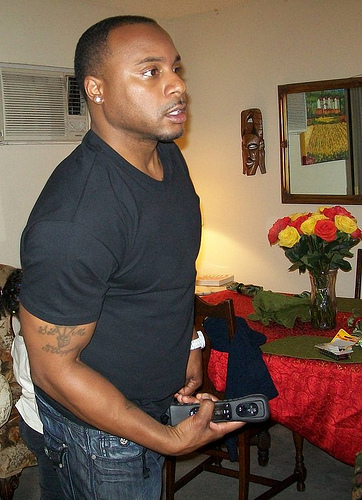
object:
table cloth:
[203, 285, 332, 429]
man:
[12, 8, 243, 497]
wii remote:
[162, 382, 276, 437]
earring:
[81, 68, 107, 109]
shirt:
[13, 127, 215, 430]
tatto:
[31, 319, 90, 363]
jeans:
[27, 397, 173, 499]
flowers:
[258, 195, 360, 334]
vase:
[304, 257, 344, 331]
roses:
[261, 200, 360, 266]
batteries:
[317, 323, 358, 359]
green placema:
[256, 322, 359, 374]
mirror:
[275, 74, 360, 208]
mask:
[236, 104, 273, 183]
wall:
[189, 10, 273, 257]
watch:
[191, 323, 214, 353]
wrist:
[185, 324, 210, 357]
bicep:
[9, 272, 108, 360]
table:
[203, 282, 360, 451]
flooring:
[178, 443, 360, 499]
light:
[202, 223, 252, 286]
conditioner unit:
[1, 57, 96, 152]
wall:
[2, 6, 79, 193]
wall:
[177, 5, 356, 280]